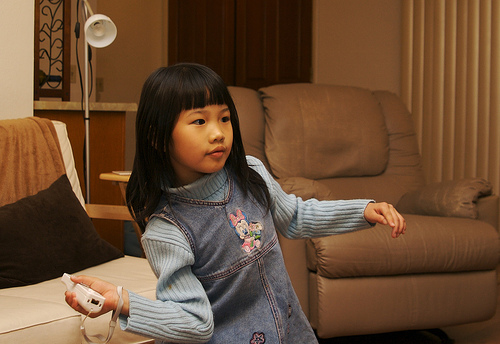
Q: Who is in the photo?
A: A girl.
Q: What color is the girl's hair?
A: Black.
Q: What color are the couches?
A: Brown.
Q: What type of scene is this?
A: Indoor.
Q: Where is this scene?
A: Living room.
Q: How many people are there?
A: One.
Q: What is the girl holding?
A: Wii controller.